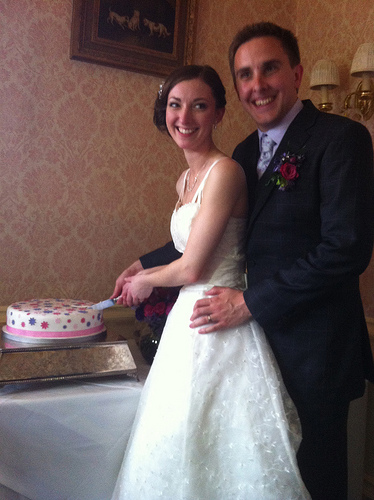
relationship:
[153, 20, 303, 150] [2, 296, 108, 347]
couple cutting cake cake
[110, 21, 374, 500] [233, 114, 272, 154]
man wears tie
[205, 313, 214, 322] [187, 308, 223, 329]
ring on finger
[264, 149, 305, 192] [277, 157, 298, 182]
boutonniere has rose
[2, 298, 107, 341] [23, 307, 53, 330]
cake has stars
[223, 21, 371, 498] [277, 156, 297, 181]
man has rose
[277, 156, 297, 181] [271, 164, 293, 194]
rose in button hole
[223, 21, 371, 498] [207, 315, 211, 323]
man wears ring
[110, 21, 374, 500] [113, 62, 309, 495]
man behind woman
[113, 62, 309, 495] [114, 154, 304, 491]
woman wears white dress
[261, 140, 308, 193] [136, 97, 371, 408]
boutonniere on jacket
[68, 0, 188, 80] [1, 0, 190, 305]
artwork on patterned wallpaper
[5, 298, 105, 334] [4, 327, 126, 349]
cake on tray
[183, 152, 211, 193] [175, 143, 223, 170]
necklace on neck